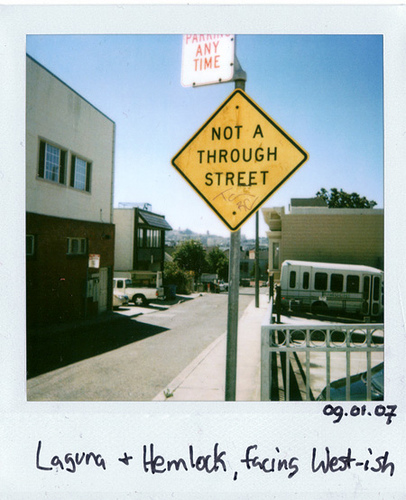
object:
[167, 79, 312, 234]
yellow sign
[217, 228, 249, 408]
steel post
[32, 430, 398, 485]
writing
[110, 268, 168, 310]
cab truck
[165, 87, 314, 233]
road signs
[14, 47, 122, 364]
building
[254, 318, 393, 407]
fence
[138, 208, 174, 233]
overhang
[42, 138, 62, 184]
windows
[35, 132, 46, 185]
shutters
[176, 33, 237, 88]
sign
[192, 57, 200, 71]
letters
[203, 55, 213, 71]
letters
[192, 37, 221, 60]
word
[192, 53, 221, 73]
word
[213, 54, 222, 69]
letters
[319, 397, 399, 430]
date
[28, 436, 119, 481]
word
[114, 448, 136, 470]
symbol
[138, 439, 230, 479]
word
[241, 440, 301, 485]
word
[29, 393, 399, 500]
description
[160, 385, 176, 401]
weed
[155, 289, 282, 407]
sidewalk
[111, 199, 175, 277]
building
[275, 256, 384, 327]
bus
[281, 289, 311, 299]
stripes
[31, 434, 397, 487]
label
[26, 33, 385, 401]
photo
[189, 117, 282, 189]
information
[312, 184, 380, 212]
tree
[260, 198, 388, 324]
building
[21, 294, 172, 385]
shadow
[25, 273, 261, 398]
street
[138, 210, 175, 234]
awning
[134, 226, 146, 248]
windows